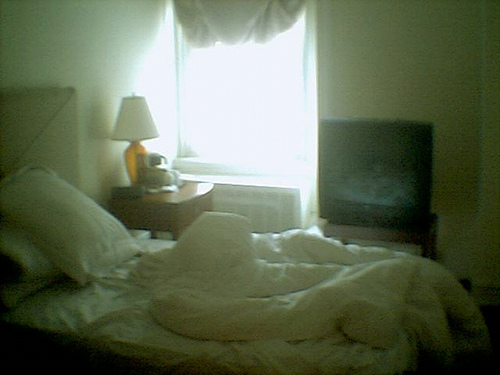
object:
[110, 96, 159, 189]
lamp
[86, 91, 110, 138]
shade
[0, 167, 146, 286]
white pillow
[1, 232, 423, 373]
bed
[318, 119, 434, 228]
tv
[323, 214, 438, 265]
stand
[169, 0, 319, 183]
window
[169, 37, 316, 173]
coming through it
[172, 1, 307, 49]
white curtain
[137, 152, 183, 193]
things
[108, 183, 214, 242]
nightstand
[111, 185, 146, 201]
alarm clock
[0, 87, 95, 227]
headboard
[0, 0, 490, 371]
room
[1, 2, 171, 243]
wall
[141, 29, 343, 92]
and blurry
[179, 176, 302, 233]
airconditioner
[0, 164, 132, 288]
horizontal pillow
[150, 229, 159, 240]
legs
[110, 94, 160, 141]
white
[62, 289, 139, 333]
wrinkles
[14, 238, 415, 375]
sheets